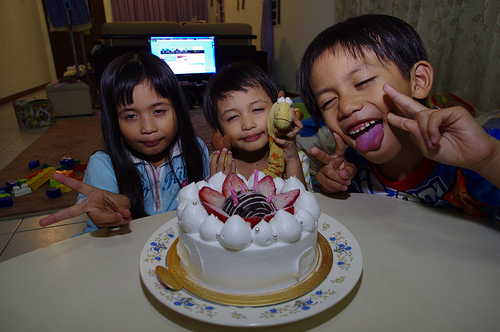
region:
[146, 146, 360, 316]
White birthday cake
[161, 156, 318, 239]
Flowers made of icing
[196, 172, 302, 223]
Flowers made of strawberries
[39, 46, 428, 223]
Three students sitting in front a cake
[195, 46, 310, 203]
Child holding a stuff giraffe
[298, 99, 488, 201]
Kid holding up the peace sign with both hands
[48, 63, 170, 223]
Little girl showing the peace sign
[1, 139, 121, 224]
Large building toys that are similar to Legos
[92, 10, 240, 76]
TV screen turned on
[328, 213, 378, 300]
White plate with blue and gold flowers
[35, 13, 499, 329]
three kids in front a cake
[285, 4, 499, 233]
kid making a V with fingers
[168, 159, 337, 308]
cake is white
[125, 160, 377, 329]
cake is on a white dish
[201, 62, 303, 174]
kid has his eyes closed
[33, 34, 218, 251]
little girl making a V with right hand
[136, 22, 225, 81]
a laptop is turn on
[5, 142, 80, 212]
toys for kids on the floor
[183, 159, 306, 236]
top of the cake is decorated with strawberry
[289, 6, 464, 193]
kid has his tongue out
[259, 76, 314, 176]
child holds toy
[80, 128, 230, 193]
girl has blue shirt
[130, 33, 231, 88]
television is on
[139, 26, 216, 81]
television is behind children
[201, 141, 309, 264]
red top on cake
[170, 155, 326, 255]
white icing on cake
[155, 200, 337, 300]
cake on gold platter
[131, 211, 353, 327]
cake on white round floral plate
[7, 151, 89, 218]
multicolored toys on floor behind children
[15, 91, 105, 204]
rug is brown behind children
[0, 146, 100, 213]
duplo blocks on a rug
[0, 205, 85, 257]
a floor of large tiles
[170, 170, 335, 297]
a cake on a plate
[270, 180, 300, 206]
a cut strawberry on a cake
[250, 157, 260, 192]
a candle in a cake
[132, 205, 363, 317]
a white cake with blue flowers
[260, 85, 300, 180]
a toy giraffe in a child's hand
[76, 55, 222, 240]
a girl holding up two fingers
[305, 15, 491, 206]
a boy holding up to fingers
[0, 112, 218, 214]
a brown rug on a tile floor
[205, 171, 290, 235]
sliced strawberries on cake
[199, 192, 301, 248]
sliced strawberries on cake